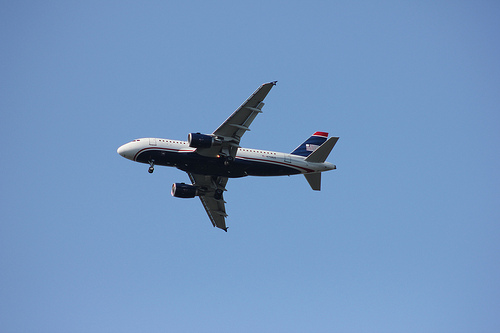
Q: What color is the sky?
A: Blue.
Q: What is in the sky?
A: A plane.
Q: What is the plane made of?
A: Metal.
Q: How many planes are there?
A: One.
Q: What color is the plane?
A: White, blue, and red.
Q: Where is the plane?
A: In the sky.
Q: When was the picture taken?
A: Daytime.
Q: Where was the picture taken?
A: In the sky.